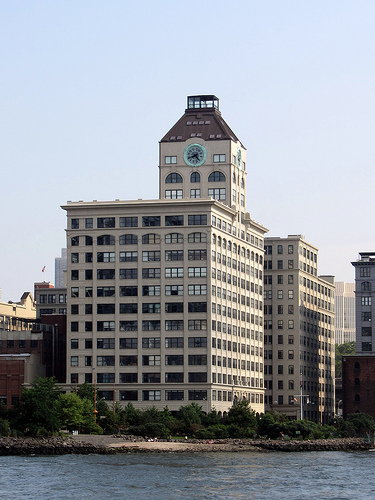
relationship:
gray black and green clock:
[188, 146, 202, 164] [186, 143, 207, 170]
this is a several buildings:
[157, 88, 249, 203] [1, 90, 374, 424]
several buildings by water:
[1, 90, 374, 424] [1, 455, 373, 498]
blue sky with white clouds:
[3, 4, 161, 133] [249, 29, 369, 215]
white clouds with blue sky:
[249, 29, 369, 215] [3, 4, 161, 133]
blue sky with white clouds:
[3, 4, 161, 133] [1, 119, 154, 194]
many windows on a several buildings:
[68, 229, 263, 404] [1, 90, 374, 424]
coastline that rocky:
[1, 432, 374, 450] [3, 437, 373, 453]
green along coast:
[8, 375, 81, 435] [3, 388, 371, 498]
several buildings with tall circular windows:
[1, 90, 374, 424] [162, 169, 228, 190]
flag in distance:
[40, 262, 49, 278] [31, 260, 56, 283]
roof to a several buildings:
[61, 198, 233, 216] [1, 90, 374, 424]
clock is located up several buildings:
[186, 143, 207, 170] [1, 90, 374, 424]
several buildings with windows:
[1, 90, 374, 424] [68, 229, 263, 404]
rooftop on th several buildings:
[61, 198, 233, 216] [1, 90, 374, 424]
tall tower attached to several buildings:
[157, 88, 249, 203] [1, 90, 374, 424]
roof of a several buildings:
[263, 234, 320, 250] [1, 90, 374, 424]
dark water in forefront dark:
[1, 455, 373, 498] [40, 430, 310, 492]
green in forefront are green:
[8, 375, 81, 435] [17, 397, 293, 427]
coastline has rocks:
[1, 432, 374, 450] [15, 423, 360, 474]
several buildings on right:
[1, 90, 374, 424] [296, 286, 370, 453]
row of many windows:
[68, 265, 210, 283] [68, 229, 263, 404]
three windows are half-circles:
[162, 169, 228, 190] [165, 174, 225, 193]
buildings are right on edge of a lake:
[1, 90, 374, 424] [21, 371, 372, 403]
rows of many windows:
[68, 265, 210, 283] [68, 229, 263, 404]